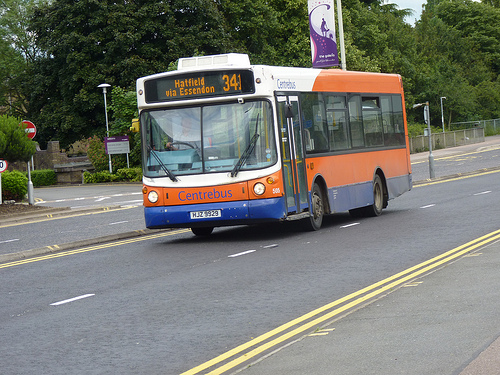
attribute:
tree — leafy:
[24, 0, 233, 144]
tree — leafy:
[250, 0, 312, 62]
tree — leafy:
[410, 16, 485, 124]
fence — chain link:
[415, 116, 498, 146]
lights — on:
[132, 178, 285, 213]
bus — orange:
[137, 63, 432, 244]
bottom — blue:
[125, 164, 427, 247]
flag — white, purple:
[305, 0, 341, 66]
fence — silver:
[410, 125, 485, 154]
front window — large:
[138, 105, 203, 177]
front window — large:
[203, 98, 277, 173]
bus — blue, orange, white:
[135, 50, 415, 244]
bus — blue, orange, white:
[130, 51, 414, 229]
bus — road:
[126, 45, 406, 240]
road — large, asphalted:
[2, 148, 493, 367]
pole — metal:
[94, 76, 114, 189]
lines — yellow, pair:
[277, 275, 385, 328]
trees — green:
[44, 5, 295, 49]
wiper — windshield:
[147, 144, 172, 179]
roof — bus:
[136, 63, 386, 81]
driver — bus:
[164, 119, 201, 151]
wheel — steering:
[157, 137, 191, 154]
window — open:
[360, 93, 382, 142]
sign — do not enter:
[19, 116, 37, 202]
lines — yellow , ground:
[207, 289, 367, 373]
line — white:
[53, 287, 97, 311]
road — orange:
[15, 232, 498, 362]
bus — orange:
[116, 49, 421, 235]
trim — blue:
[130, 183, 409, 225]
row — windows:
[281, 87, 409, 149]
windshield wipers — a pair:
[142, 130, 272, 181]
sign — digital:
[141, 60, 261, 98]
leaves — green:
[412, 43, 438, 78]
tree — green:
[185, 2, 316, 67]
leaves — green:
[430, 39, 457, 88]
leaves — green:
[452, 65, 491, 112]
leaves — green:
[472, 6, 492, 40]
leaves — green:
[431, 16, 461, 73]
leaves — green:
[42, 87, 71, 126]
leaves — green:
[58, 62, 89, 102]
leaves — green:
[52, 46, 116, 73]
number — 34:
[213, 69, 239, 95]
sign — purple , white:
[104, 135, 130, 156]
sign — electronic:
[154, 70, 241, 99]